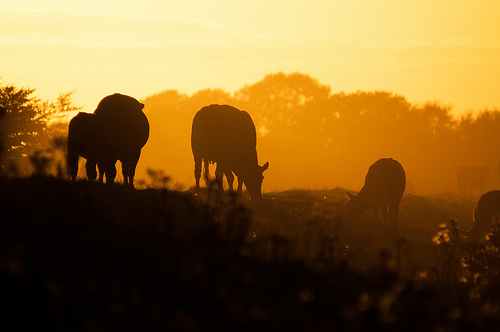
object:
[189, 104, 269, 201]
animal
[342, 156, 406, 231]
animal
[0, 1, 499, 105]
sky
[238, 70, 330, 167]
foliage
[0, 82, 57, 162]
trees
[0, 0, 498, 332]
background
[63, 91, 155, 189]
cows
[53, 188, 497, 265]
pasture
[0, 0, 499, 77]
clouds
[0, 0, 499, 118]
sun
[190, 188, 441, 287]
grass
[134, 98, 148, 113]
ear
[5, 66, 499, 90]
horizon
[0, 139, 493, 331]
vegetation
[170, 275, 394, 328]
front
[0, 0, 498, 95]
light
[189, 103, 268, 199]
shilouette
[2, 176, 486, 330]
hill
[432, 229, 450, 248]
flowers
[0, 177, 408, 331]
bushes